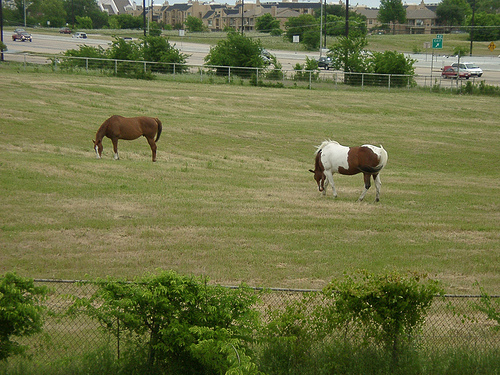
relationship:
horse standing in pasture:
[307, 126, 404, 204] [3, 60, 499, 287]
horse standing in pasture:
[92, 112, 162, 163] [3, 60, 499, 287]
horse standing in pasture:
[307, 126, 404, 204] [6, 63, 496, 372]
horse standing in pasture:
[92, 112, 162, 163] [6, 63, 496, 372]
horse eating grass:
[92, 112, 162, 163] [1, 67, 498, 276]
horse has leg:
[92, 112, 162, 163] [147, 134, 159, 163]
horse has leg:
[92, 112, 162, 163] [111, 140, 120, 163]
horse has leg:
[307, 126, 404, 204] [362, 169, 374, 200]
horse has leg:
[307, 126, 404, 204] [373, 172, 381, 202]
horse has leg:
[307, 126, 404, 204] [320, 168, 336, 200]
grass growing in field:
[2, 64, 496, 302] [2, 66, 494, 281]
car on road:
[256, 48, 273, 63] [267, 47, 287, 64]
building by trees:
[401, 3, 438, 35] [115, 3, 485, 36]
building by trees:
[351, 3, 383, 33] [115, 3, 485, 36]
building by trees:
[274, 5, 303, 32] [115, 3, 485, 36]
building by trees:
[164, 3, 193, 30] [115, 3, 485, 36]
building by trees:
[202, 3, 239, 35] [115, 3, 485, 36]